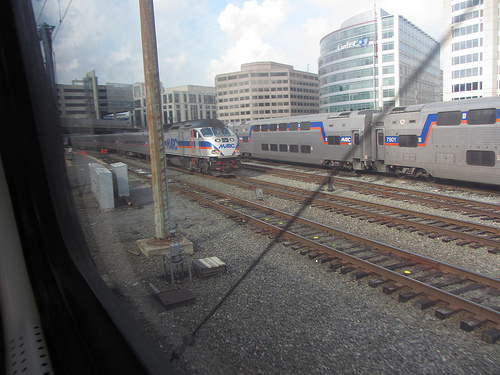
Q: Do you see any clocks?
A: No, there are no clocks.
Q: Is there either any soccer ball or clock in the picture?
A: No, there are no clocks or soccer balls.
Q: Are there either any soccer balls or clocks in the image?
A: No, there are no clocks or soccer balls.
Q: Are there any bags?
A: No, there are no bags.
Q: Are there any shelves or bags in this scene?
A: No, there are no bags or shelves.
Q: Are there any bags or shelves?
A: No, there are no bags or shelves.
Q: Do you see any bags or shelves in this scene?
A: No, there are no bags or shelves.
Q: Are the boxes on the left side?
A: Yes, the boxes are on the left of the image.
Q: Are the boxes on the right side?
A: No, the boxes are on the left of the image.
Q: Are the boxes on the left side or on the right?
A: The boxes are on the left of the image.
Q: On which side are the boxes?
A: The boxes are on the left of the image.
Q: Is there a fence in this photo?
A: No, there are no fences.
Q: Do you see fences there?
A: No, there are no fences.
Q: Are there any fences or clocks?
A: No, there are no fences or clocks.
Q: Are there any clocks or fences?
A: No, there are no fences or clocks.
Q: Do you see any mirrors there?
A: No, there are no mirrors.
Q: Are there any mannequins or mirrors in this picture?
A: No, there are no mirrors or mannequins.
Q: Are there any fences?
A: No, there are no fences.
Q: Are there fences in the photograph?
A: No, there are no fences.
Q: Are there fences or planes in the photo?
A: No, there are no fences or planes.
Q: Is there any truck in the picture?
A: No, there are no trucks.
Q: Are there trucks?
A: No, there are no trucks.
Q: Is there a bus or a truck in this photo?
A: No, there are no trucks or buses.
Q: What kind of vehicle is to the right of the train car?
A: The vehicle is a car.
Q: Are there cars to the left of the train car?
A: No, the car is to the right of the train car.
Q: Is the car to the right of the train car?
A: Yes, the car is to the right of the train car.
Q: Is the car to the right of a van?
A: No, the car is to the right of the train car.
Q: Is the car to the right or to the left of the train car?
A: The car is to the right of the train car.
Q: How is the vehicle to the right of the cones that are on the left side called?
A: The vehicle is a car.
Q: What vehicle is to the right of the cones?
A: The vehicle is a car.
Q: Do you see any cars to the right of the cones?
A: Yes, there is a car to the right of the cones.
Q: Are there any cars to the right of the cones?
A: Yes, there is a car to the right of the cones.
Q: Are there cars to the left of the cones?
A: No, the car is to the right of the cones.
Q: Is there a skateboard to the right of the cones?
A: No, there is a car to the right of the cones.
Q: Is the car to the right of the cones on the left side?
A: Yes, the car is to the right of the cones.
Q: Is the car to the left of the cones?
A: No, the car is to the right of the cones.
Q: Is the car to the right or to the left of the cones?
A: The car is to the right of the cones.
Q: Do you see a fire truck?
A: No, there are no fire trucks.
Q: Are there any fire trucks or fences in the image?
A: No, there are no fire trucks or fences.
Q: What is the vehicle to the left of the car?
A: The vehicle is a train car.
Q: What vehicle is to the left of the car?
A: The vehicle is a train car.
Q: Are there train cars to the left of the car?
A: Yes, there is a train car to the left of the car.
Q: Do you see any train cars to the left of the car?
A: Yes, there is a train car to the left of the car.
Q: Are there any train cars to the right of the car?
A: No, the train car is to the left of the car.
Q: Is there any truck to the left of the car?
A: No, there is a train car to the left of the car.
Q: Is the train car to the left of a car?
A: Yes, the train car is to the left of a car.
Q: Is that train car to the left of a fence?
A: No, the train car is to the left of a car.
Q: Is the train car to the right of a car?
A: No, the train car is to the left of a car.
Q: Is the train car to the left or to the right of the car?
A: The train car is to the left of the car.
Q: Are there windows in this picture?
A: Yes, there is a window.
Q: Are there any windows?
A: Yes, there is a window.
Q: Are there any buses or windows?
A: Yes, there is a window.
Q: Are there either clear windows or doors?
A: Yes, there is a clear window.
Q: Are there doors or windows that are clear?
A: Yes, the window is clear.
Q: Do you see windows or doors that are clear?
A: Yes, the window is clear.